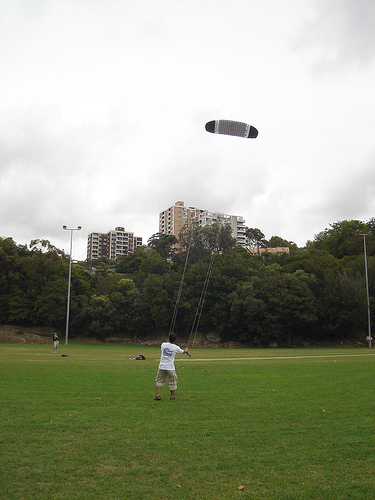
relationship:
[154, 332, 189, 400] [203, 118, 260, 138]
guy flying kite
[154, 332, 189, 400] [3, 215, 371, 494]
guy in park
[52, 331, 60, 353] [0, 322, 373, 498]
girl are in park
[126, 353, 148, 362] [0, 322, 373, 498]
people are in park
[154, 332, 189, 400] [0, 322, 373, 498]
guy are in park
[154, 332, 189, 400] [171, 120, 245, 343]
guy holding kite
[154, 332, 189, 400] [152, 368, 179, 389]
guy wearing shorts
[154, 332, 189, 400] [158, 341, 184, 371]
guy wearing shirt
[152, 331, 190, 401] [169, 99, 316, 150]
guy flying kite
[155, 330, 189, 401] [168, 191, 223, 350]
kite flyer using strings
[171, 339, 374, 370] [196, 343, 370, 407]
line on ground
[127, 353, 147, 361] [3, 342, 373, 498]
people laying on ground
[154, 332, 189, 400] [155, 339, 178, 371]
guy wearing shirt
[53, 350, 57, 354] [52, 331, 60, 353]
shoe on girl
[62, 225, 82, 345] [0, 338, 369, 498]
light pole in field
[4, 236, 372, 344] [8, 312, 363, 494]
tree lining park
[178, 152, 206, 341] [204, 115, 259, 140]
strings attached kite